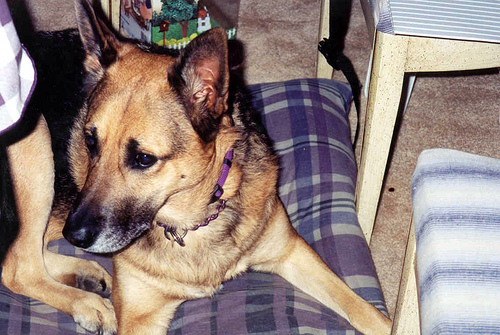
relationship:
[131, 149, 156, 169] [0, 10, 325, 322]
eye of dog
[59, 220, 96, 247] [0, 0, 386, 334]
nose on dog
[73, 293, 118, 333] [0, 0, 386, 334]
paw on dog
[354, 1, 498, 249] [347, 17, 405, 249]
table has leg